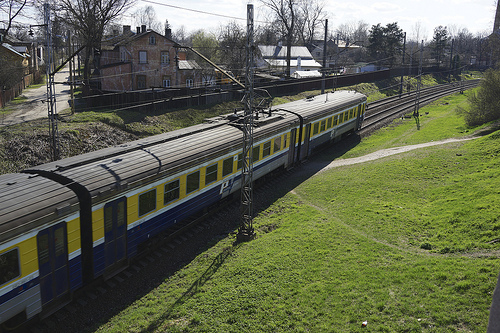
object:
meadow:
[53, 82, 500, 333]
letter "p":
[219, 181, 228, 195]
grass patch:
[65, 128, 80, 133]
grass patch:
[0, 158, 18, 168]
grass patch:
[71, 86, 82, 94]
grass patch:
[4, 131, 26, 135]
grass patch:
[144, 126, 161, 134]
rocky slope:
[0, 122, 140, 175]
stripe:
[83, 132, 243, 188]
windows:
[164, 179, 179, 206]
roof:
[17, 121, 248, 197]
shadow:
[0, 131, 361, 333]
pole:
[321, 19, 328, 94]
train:
[1, 90, 368, 331]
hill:
[0, 67, 491, 174]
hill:
[27, 84, 500, 333]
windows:
[163, 76, 171, 87]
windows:
[160, 51, 169, 65]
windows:
[139, 51, 147, 64]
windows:
[150, 35, 156, 45]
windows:
[186, 79, 194, 87]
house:
[178, 59, 204, 88]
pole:
[241, 4, 254, 241]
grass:
[287, 133, 500, 248]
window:
[138, 188, 157, 217]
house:
[99, 25, 181, 94]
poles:
[43, 3, 60, 162]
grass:
[367, 86, 401, 103]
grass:
[328, 88, 494, 161]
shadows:
[413, 115, 420, 130]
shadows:
[54, 114, 155, 137]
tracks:
[360, 84, 479, 131]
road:
[0, 52, 83, 126]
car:
[262, 90, 368, 164]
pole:
[69, 29, 74, 114]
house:
[253, 46, 323, 79]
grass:
[31, 131, 500, 333]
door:
[103, 196, 128, 276]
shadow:
[136, 241, 242, 333]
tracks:
[363, 82, 478, 121]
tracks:
[365, 79, 482, 111]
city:
[0, 21, 500, 126]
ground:
[0, 30, 500, 333]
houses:
[1, 29, 31, 104]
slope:
[112, 110, 169, 134]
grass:
[75, 111, 112, 122]